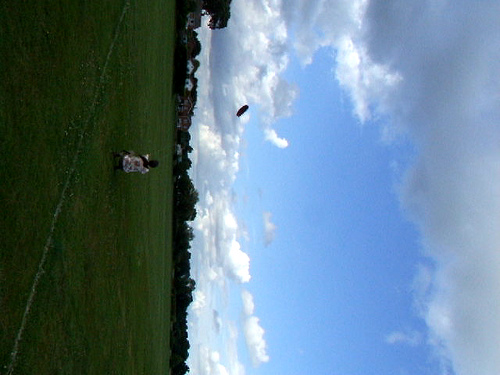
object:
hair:
[147, 159, 157, 169]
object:
[235, 104, 249, 118]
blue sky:
[241, 47, 444, 375]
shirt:
[120, 152, 150, 176]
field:
[0, 2, 178, 373]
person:
[112, 150, 159, 175]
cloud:
[187, 0, 300, 375]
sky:
[182, 0, 499, 374]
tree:
[178, 0, 230, 32]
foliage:
[168, 0, 233, 374]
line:
[0, 36, 118, 373]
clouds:
[280, 0, 498, 374]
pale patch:
[113, 286, 129, 330]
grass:
[0, 0, 179, 374]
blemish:
[134, 154, 151, 170]